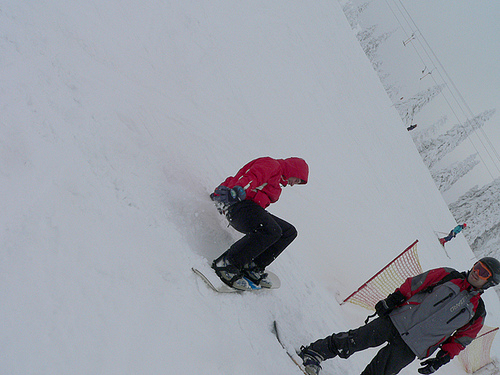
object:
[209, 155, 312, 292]
person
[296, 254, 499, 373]
man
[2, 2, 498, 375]
snow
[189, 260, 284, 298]
snowboard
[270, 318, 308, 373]
snowboard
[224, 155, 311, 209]
jacket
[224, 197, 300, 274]
pants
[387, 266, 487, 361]
coat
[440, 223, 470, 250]
person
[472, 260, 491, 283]
goggles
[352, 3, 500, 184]
wires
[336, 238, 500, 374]
fence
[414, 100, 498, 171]
tree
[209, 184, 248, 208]
glove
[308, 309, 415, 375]
pants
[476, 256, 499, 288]
helmet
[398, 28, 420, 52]
ski lift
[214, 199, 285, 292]
leg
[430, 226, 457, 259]
ski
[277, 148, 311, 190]
head